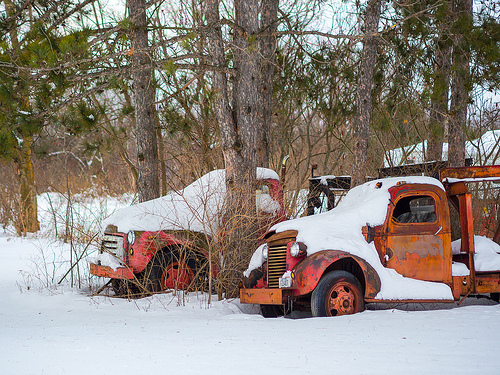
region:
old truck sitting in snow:
[235, 158, 498, 315]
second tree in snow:
[81, 155, 384, 301]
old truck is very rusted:
[236, 154, 497, 331]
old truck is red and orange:
[235, 146, 499, 327]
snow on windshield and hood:
[243, 170, 453, 312]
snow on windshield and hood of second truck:
[93, 153, 284, 249]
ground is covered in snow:
[2, 187, 498, 374]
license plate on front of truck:
[273, 268, 295, 288]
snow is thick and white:
[0, 180, 497, 372]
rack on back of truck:
[433, 155, 498, 301]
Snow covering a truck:
[271, 161, 448, 308]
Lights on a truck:
[259, 242, 306, 263]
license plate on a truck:
[273, 272, 299, 288]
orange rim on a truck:
[334, 285, 353, 313]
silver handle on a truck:
[433, 224, 448, 238]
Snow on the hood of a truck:
[303, 180, 375, 237]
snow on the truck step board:
[373, 267, 443, 304]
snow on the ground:
[83, 300, 271, 361]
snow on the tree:
[6, 132, 28, 154]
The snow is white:
[103, 314, 226, 369]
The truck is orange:
[376, 196, 461, 303]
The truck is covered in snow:
[268, 168, 413, 290]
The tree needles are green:
[26, 84, 114, 158]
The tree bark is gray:
[222, 109, 267, 272]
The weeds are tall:
[151, 176, 278, 335]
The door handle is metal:
[430, 218, 447, 243]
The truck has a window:
[377, 177, 451, 244]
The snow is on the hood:
[119, 174, 220, 286]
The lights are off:
[286, 240, 313, 265]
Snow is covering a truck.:
[260, 163, 435, 322]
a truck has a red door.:
[376, 165, 458, 288]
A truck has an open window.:
[376, 183, 445, 233]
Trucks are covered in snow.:
[98, 155, 428, 317]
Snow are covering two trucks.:
[71, 164, 432, 345]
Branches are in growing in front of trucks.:
[61, 211, 258, 305]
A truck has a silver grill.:
[80, 221, 154, 291]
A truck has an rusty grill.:
[235, 240, 323, 324]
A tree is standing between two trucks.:
[184, 2, 284, 308]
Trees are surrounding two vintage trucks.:
[49, 90, 498, 337]